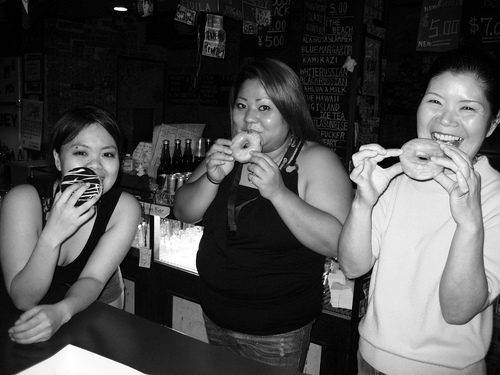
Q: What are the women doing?
A: Eating.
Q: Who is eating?
A: The women.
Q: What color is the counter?
A: Black.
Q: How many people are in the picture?
A: Three.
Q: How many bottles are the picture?
A: Four.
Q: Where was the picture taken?
A: In a restaurant.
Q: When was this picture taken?
A: At night.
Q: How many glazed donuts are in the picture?
A: Two.